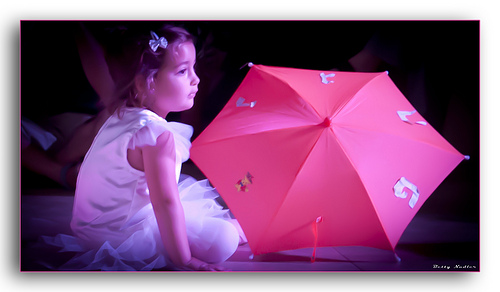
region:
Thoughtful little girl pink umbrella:
[77, 21, 459, 262]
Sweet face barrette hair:
[115, 24, 210, 120]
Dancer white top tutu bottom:
[89, 64, 236, 268]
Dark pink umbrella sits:
[197, 58, 461, 260]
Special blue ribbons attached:
[311, 69, 433, 224]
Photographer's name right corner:
[425, 255, 481, 275]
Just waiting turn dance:
[159, 32, 255, 269]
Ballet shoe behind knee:
[190, 203, 256, 264]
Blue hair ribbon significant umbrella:
[139, 25, 176, 59]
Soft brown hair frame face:
[102, 28, 191, 110]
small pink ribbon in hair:
[133, 22, 175, 56]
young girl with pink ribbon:
[75, 26, 210, 126]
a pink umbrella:
[206, 43, 445, 263]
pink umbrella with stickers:
[223, 47, 452, 244]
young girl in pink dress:
[41, 23, 240, 273]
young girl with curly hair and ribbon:
[92, 22, 209, 135]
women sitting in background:
[29, 21, 132, 193]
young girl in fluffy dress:
[36, 19, 247, 270]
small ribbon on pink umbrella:
[295, 189, 340, 263]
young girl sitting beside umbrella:
[53, 26, 475, 268]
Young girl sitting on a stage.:
[82, 28, 242, 270]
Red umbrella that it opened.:
[176, 44, 471, 259]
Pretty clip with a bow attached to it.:
[137, 30, 174, 57]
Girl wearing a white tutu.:
[42, 177, 238, 269]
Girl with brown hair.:
[102, 22, 214, 134]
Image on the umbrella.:
[224, 159, 263, 199]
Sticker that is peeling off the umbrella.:
[387, 167, 434, 233]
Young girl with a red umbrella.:
[66, 21, 471, 268]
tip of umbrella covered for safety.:
[241, 55, 257, 71]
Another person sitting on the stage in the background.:
[24, 24, 131, 214]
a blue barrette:
[141, 27, 178, 54]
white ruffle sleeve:
[128, 115, 188, 147]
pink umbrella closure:
[296, 202, 346, 262]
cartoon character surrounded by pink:
[229, 161, 274, 201]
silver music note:
[226, 86, 263, 120]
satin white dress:
[71, 116, 153, 265]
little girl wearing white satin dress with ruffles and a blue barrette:
[58, 28, 237, 260]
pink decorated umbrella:
[196, 64, 466, 263]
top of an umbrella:
[308, 111, 348, 142]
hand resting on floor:
[161, 238, 234, 268]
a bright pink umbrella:
[188, 45, 470, 258]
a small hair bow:
[136, 30, 175, 60]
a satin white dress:
[56, 83, 248, 263]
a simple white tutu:
[56, 172, 241, 274]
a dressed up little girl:
[62, 31, 273, 265]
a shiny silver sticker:
[385, 162, 428, 217]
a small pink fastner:
[296, 201, 333, 270]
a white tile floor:
[6, 200, 463, 265]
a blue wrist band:
[51, 155, 83, 196]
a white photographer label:
[422, 255, 479, 270]